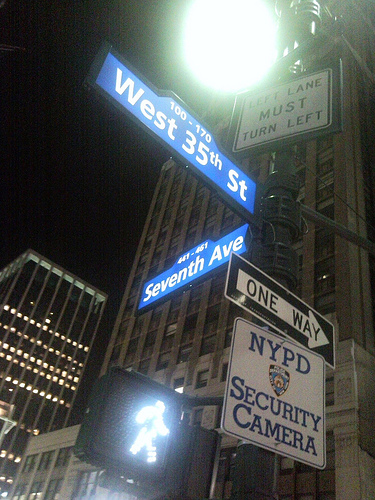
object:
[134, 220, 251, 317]
street sign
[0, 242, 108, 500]
building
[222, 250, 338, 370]
one-way sign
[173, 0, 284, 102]
light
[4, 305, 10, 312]
lights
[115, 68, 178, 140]
west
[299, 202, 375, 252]
pole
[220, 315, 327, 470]
sign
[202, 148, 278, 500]
street pole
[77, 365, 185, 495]
sign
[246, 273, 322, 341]
one way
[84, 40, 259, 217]
sign